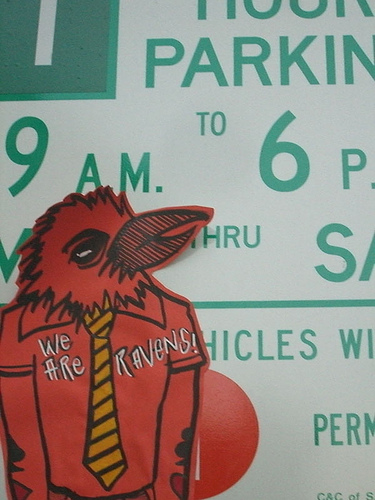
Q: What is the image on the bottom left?
A: Bird.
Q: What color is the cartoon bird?
A: Red.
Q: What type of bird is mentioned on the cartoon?
A: Ravens.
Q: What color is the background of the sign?
A: White.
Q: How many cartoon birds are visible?
A: One.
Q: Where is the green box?
A: Top left corner.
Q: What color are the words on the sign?
A: Green.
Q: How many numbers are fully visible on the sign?
A: Two.